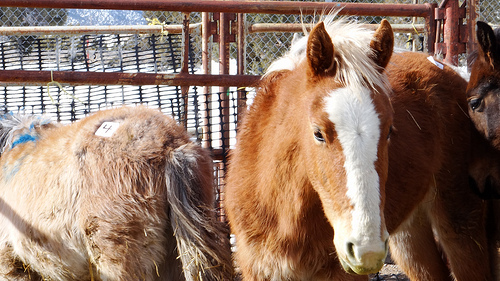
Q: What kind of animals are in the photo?
A: Ponies.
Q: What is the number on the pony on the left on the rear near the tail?
A: 4.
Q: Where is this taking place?
A: In a zoo.